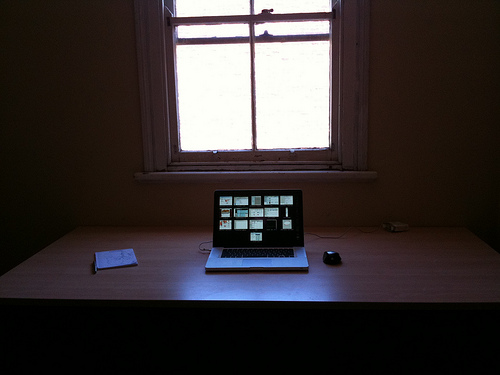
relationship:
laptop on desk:
[206, 190, 308, 272] [0, 228, 500, 372]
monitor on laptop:
[218, 193, 296, 242] [206, 190, 308, 272]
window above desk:
[174, 0, 333, 153] [0, 228, 500, 372]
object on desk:
[383, 220, 410, 234] [0, 228, 500, 372]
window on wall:
[174, 0, 333, 153] [0, 1, 500, 278]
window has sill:
[174, 0, 333, 153] [135, 0, 377, 181]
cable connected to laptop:
[304, 223, 387, 239] [206, 190, 308, 272]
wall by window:
[0, 1, 500, 278] [174, 0, 333, 153]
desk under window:
[0, 228, 500, 372] [174, 0, 333, 153]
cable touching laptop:
[304, 223, 387, 239] [206, 190, 308, 272]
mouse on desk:
[324, 250, 344, 267] [0, 228, 500, 372]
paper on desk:
[94, 247, 139, 271] [0, 228, 500, 372]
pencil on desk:
[92, 250, 98, 273] [0, 228, 500, 372]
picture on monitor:
[250, 232, 263, 242] [218, 193, 296, 242]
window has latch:
[174, 0, 333, 153] [258, 7, 275, 14]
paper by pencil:
[94, 247, 139, 271] [92, 250, 98, 273]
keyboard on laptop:
[221, 247, 295, 257] [206, 190, 308, 272]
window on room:
[174, 0, 333, 153] [0, 2, 499, 374]